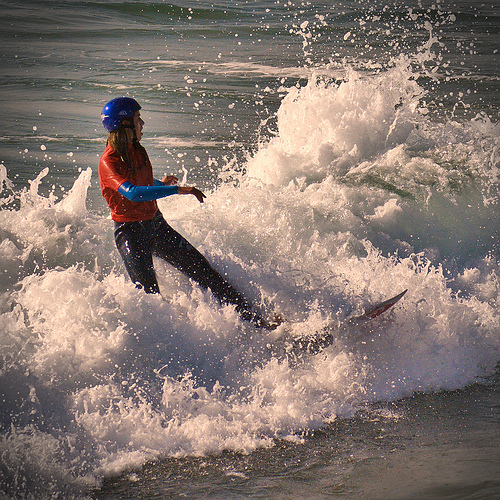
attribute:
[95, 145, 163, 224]
shirt — orange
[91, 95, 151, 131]
helmet — blue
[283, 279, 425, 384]
surfboard — white, red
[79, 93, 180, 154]
safety helmet — blue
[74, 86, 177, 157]
blue helmet — safety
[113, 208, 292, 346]
blue wetsuit — orange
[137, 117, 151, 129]
he nose — pointy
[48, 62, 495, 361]
crushing wave — white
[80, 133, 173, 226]
orange shirts — blue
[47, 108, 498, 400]
waves in ocean — white , gray 